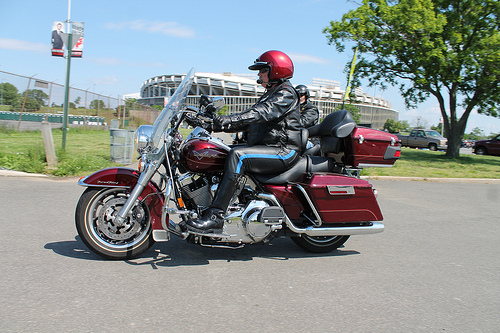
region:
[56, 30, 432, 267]
a motorcycle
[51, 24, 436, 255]
a maroon motorcyle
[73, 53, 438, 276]
a motorcycle driving on a road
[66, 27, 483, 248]
a man rides a motorcycle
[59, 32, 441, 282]
a man on a motorcycle has a red helmet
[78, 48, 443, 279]
the rider is wearing a helmet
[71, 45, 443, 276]
the man on the motorcycle is wearing black leather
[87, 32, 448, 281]
two motorcycles are on a road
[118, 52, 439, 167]
a stadium is beside the road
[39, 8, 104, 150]
a sign hangs on a pole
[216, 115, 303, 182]
blue stripe on pants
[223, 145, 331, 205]
blue stripe on pants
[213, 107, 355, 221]
blue stripe on pants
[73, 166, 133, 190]
fender of a motorcycle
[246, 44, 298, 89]
a red motorcycle helmet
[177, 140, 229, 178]
gas tank on a motorcycle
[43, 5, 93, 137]
sign on a pole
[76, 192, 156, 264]
wheel on a motorcycl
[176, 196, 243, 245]
a black leather boot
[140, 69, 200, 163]
windshield on a motorcycle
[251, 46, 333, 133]
men in leather jackets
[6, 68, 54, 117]
a chain length fence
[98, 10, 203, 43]
a cloud in the sky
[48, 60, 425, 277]
man riding red motorcycle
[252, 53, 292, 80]
Red helmet on motorcycle rider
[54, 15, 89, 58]
Sign with man and lettering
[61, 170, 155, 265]
Front tire of motorcycle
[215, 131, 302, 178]
Black leather pants with blue line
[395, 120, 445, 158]
Tan truck in the distance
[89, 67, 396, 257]
Man riding red motorcycle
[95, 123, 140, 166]
Silver trash can in grass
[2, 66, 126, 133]
Tall barbed-wire fence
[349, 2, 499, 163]
Large tree with green leaves and brown branches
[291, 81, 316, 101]
Black helmet on man in background